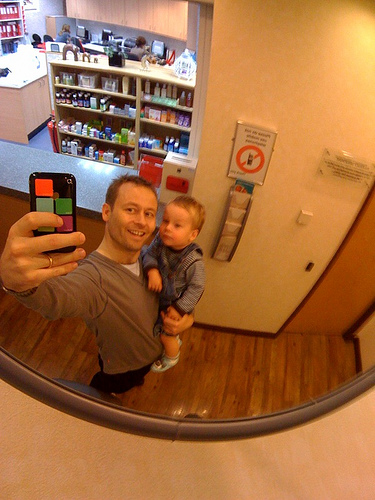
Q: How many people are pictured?
A: 4.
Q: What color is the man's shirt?
A: Brown.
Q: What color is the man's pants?
A: Black.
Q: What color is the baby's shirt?
A: Grey.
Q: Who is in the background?
A: Pharmacist.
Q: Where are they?
A: A pharmacy.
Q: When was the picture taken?
A: During business hours.